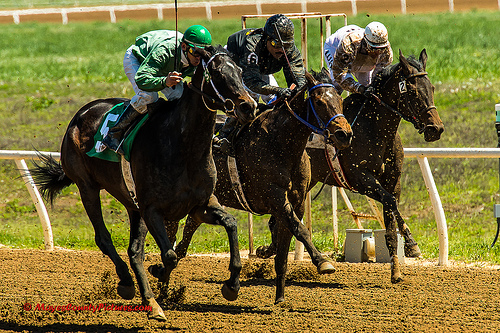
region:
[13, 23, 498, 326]
3 Brown horses with blue reins.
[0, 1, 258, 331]
Horse with number 5 on side.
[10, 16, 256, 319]
Man wearing green helmet riding horse.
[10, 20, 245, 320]
Man wearing long jockey pants riding horse.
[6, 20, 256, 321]
Man wearing long black boots riding horse.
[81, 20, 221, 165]
Man with eye glasses on.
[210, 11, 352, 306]
Man with black helmet on riding horse.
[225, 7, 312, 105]
Man with black jacket on.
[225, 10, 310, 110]
Man with number 6 on black jacket.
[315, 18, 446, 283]
Man wearing white jacket and white helmet riding horse.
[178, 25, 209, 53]
green riding helmet on jockey's head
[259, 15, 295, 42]
black riding helmet on jockey's head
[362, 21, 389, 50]
white riding helmet on jockey's head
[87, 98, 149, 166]
green racing saddle on horse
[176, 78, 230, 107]
reins in jockey's hands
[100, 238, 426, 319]
hooves of horses running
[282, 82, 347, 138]
blue horse bridle on horse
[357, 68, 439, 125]
brown horse bridle on horse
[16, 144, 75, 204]
tail on horse's rump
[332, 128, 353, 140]
nostrils on horse's face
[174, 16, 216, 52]
Green helmet on a man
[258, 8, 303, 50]
Black helmet on a man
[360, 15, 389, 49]
White helmet on a man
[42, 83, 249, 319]
LArge brown horse racing on a dirt track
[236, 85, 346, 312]
LArge brown horse racing on a dirt track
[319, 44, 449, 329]
LArge brown horse racing on a dirt track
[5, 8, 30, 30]
Large white metal post in the ground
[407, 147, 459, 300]
Large white metal post in the ground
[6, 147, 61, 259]
Large white metal post in the ground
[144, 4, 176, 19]
Large white metal post in the ground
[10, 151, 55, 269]
Long white metal post in the dirt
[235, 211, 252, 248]
Long white metal post in the dirt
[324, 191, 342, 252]
Long white metal post in the dirt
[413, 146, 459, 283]
Long white metal post in the dirt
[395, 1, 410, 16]
Long white metal post in the dirt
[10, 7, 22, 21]
Long white metal post in the dirt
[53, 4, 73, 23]
Long white metal post in the dirt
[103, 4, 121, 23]
Long white metal post in the dirt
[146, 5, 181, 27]
Long white metal post in the dirt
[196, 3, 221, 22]
Long white metal post in the dirt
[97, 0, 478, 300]
the horses are in motion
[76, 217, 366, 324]
the dirt is being kicked up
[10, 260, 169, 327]
red writing on the bottom left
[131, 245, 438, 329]
the dirt is brown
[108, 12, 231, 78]
the man is bending forward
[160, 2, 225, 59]
the man is wearing a helmet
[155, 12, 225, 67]
the helmet is green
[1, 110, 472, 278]
the rail is on the right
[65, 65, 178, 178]
the man is wearing riding boots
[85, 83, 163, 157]
the boots are black